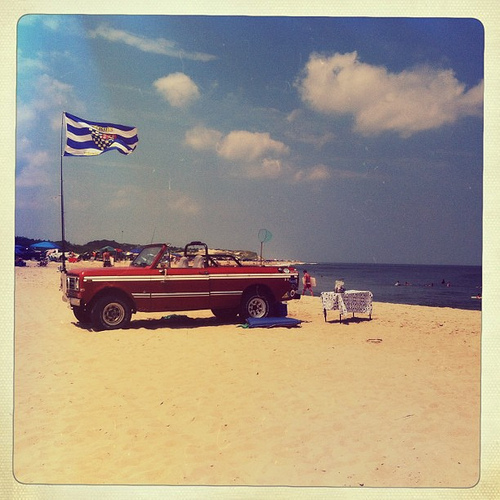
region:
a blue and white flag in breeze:
[55, 98, 146, 168]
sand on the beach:
[222, 366, 334, 415]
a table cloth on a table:
[316, 281, 379, 328]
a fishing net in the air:
[250, 222, 279, 264]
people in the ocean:
[388, 266, 459, 298]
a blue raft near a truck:
[237, 305, 308, 338]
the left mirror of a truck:
[152, 257, 176, 283]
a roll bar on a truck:
[179, 236, 249, 270]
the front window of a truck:
[128, 242, 169, 277]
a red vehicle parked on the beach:
[53, 237, 305, 334]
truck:
[64, 241, 295, 341]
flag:
[48, 98, 149, 178]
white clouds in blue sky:
[330, 48, 407, 123]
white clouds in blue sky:
[391, 132, 423, 159]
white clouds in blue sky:
[198, 123, 283, 181]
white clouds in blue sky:
[167, 22, 232, 109]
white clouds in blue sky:
[347, 129, 411, 174]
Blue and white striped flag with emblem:
[60, 110, 142, 162]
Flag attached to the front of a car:
[58, 107, 308, 328]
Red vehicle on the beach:
[58, 238, 305, 330]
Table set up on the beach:
[318, 289, 374, 325]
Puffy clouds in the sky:
[151, 94, 481, 192]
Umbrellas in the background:
[14, 239, 144, 265]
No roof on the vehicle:
[133, 241, 255, 273]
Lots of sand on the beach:
[16, 254, 491, 491]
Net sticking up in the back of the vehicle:
[254, 227, 275, 267]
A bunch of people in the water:
[385, 277, 484, 302]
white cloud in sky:
[288, 42, 440, 131]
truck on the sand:
[53, 233, 311, 351]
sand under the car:
[112, 332, 222, 403]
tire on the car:
[83, 276, 155, 336]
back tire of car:
[226, 272, 282, 339]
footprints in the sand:
[143, 363, 283, 438]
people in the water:
[399, 262, 469, 304]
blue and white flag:
[56, 89, 169, 197]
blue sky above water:
[206, 29, 295, 96]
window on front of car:
[114, 234, 178, 277]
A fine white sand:
[164, 378, 282, 428]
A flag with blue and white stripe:
[56, 105, 142, 155]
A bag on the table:
[329, 277, 356, 296]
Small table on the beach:
[318, 291, 385, 323]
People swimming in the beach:
[389, 270, 462, 293]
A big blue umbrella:
[28, 237, 57, 266]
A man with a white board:
[299, 266, 319, 296]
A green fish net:
[252, 222, 274, 272]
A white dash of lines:
[121, 264, 237, 315]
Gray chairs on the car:
[170, 255, 209, 267]